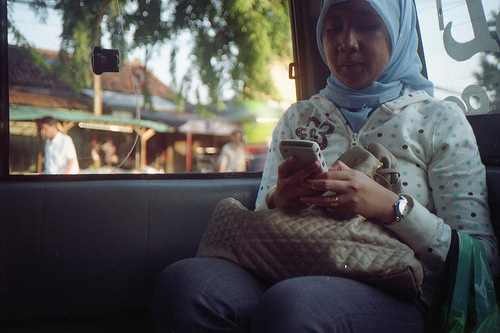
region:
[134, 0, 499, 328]
woman wearing blue burka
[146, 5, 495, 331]
woman holding white cell phone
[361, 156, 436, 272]
silver watch in left wrist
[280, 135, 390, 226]
gold ring on left ring finger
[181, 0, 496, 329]
woman holding tan purse on lap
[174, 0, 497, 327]
woman wearing grey pants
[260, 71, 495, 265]
hoodie with polka dots and flower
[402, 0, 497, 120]
decal on back window of cab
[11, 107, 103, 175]
man walking outside of vehicle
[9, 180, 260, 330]
grey interior of vehicle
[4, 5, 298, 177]
Man walking by as seen through car window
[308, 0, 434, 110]
Woman wearing blue head scarf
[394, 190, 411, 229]
Wrist wearing silver watch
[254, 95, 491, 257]
Woman wearing polka dot sweater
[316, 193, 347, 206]
Gold wearing ring on finger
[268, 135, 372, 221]
Two hands clasping cellphone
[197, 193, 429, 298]
Grey purse sitting in lap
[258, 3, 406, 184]
Woman looking down at cellphone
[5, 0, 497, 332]
Woman sitting in vehicle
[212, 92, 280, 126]
Blurry green umbrella in background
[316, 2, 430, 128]
blue scarf on head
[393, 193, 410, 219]
silver watch on wrist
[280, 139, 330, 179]
white cell phone in hand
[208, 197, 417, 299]
tan leather purse in lap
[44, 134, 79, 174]
white cotton tee shirt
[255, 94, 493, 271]
white floral cardigan sweater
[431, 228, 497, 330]
shopping bag on arm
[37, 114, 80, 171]
man walking on sidewalk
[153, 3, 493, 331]
person sitting in car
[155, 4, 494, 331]
woman looking at phone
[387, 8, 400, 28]
woman wearing blue kemar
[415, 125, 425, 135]
burgandy dot on jacket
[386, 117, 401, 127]
blue dot on jacket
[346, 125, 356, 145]
white zipper on jacket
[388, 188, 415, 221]
watch on womans wrist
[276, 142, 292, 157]
camera on back of cellphone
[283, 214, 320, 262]
woman with beige purse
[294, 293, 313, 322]
woman wearing blue jeans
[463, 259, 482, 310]
green strap on womans arm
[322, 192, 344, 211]
gold ring on womans finger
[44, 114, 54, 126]
man has black hair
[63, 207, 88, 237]
grey interior lining car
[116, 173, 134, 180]
black outline around window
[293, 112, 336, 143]
gold star on jacket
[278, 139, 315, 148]
black on top of phone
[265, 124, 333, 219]
cellphone in womans hand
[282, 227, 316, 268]
purse on womans lap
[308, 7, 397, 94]
woman looking down at phone